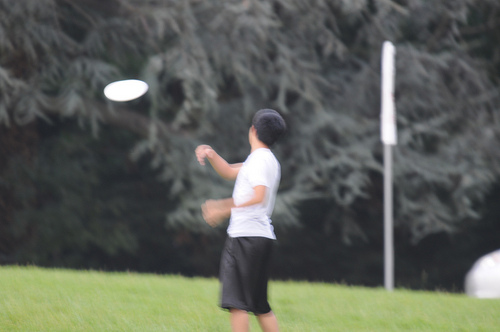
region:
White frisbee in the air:
[78, 65, 156, 115]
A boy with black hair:
[217, 93, 297, 168]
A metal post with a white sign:
[368, 43, 413, 291]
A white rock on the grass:
[442, 232, 498, 319]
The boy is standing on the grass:
[11, 89, 480, 326]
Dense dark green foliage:
[22, 22, 452, 271]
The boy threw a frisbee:
[98, 70, 301, 326]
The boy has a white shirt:
[194, 110, 298, 256]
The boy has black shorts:
[198, 212, 300, 324]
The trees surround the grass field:
[3, 217, 450, 330]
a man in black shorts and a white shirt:
[186, 96, 294, 327]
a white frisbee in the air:
[98, 68, 153, 108]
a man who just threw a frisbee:
[181, 96, 307, 326]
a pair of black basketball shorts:
[211, 223, 283, 315]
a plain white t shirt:
[218, 144, 287, 246]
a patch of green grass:
[4, 253, 499, 329]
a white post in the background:
[366, 31, 411, 290]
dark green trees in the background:
[9, 2, 487, 295]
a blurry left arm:
[189, 181, 276, 227]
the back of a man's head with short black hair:
[239, 105, 289, 154]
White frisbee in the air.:
[102, 69, 164, 128]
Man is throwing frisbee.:
[154, 80, 321, 264]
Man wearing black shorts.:
[212, 225, 267, 317]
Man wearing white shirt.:
[221, 170, 291, 257]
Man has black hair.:
[244, 95, 346, 220]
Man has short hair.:
[241, 87, 308, 187]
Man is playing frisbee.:
[42, 57, 352, 276]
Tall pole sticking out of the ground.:
[356, 70, 441, 325]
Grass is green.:
[62, 252, 168, 322]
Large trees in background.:
[95, 34, 450, 220]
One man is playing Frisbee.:
[95, 60, 305, 313]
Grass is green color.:
[21, 275, 176, 317]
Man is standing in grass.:
[20, 272, 435, 328]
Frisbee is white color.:
[100, 75, 155, 101]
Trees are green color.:
[52, 30, 335, 96]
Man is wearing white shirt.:
[205, 155, 281, 240]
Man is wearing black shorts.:
[212, 222, 277, 319]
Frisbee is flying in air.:
[97, 67, 168, 124]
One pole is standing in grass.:
[376, 47, 402, 284]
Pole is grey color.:
[371, 42, 405, 287]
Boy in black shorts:
[194, 85, 297, 330]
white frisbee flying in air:
[92, 62, 174, 119]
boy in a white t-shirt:
[174, 85, 309, 327]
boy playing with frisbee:
[88, 64, 335, 329]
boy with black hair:
[182, 105, 330, 329]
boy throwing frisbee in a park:
[46, 48, 377, 328]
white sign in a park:
[339, 24, 462, 317]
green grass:
[6, 256, 119, 330]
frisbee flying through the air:
[44, 13, 188, 153]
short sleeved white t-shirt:
[221, 137, 281, 241]